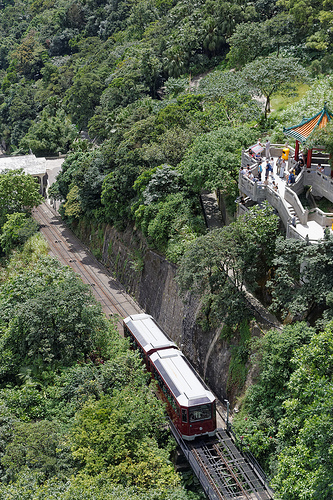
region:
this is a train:
[132, 310, 191, 391]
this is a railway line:
[204, 439, 239, 487]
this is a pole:
[221, 395, 234, 425]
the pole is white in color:
[223, 399, 231, 421]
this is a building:
[292, 111, 330, 136]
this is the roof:
[296, 119, 314, 133]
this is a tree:
[27, 290, 84, 335]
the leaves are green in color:
[51, 299, 74, 337]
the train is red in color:
[179, 422, 199, 431]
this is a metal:
[213, 467, 239, 488]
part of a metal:
[201, 471, 210, 487]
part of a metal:
[204, 440, 231, 471]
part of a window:
[191, 395, 210, 422]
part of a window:
[194, 402, 203, 416]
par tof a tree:
[125, 446, 147, 473]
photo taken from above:
[4, 257, 316, 486]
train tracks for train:
[196, 450, 254, 497]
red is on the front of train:
[178, 407, 216, 433]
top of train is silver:
[123, 312, 205, 406]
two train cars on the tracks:
[125, 312, 212, 438]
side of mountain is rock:
[95, 218, 222, 328]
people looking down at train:
[248, 144, 288, 201]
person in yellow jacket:
[278, 147, 294, 166]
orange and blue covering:
[290, 108, 331, 128]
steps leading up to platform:
[272, 186, 303, 229]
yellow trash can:
[282, 148, 289, 158]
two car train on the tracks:
[122, 311, 216, 441]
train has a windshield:
[188, 404, 212, 424]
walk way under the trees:
[197, 186, 222, 230]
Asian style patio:
[284, 108, 330, 164]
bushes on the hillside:
[226, 326, 330, 492]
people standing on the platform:
[243, 139, 295, 187]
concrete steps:
[283, 204, 302, 225]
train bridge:
[21, 173, 45, 193]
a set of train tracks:
[35, 202, 265, 496]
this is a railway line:
[87, 274, 108, 292]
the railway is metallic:
[94, 277, 110, 298]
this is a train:
[117, 312, 222, 439]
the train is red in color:
[181, 425, 190, 432]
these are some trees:
[117, 104, 198, 174]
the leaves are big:
[81, 407, 133, 463]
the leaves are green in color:
[73, 413, 124, 464]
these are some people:
[249, 133, 306, 187]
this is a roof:
[303, 116, 323, 139]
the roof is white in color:
[186, 382, 191, 387]